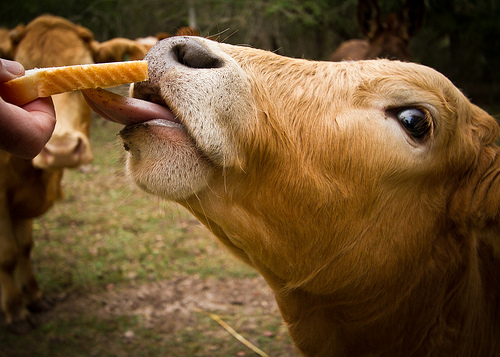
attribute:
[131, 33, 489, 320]
cow — brown, looking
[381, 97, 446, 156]
eye — brown, white, dark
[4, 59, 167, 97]
bread — brown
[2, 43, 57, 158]
hand — curled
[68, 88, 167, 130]
tongue — pink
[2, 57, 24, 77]
fingernail — clean, clear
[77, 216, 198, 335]
grass — green, brown, short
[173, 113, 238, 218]
whiskers — white, long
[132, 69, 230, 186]
mouth — white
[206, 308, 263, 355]
straw — yellow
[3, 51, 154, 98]
edge — brown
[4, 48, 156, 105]
bread — white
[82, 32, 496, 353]
animal — furry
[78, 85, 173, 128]
tongue — pink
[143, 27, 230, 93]
nose — white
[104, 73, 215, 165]
mouth area — white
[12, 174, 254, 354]
grass. — green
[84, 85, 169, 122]
tongue — red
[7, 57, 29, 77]
nail — thumb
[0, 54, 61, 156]
hand — person's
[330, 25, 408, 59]
animal — Dark brown 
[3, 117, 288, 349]
grass — green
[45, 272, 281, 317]
burn patch — big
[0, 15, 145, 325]
animal — caramel colored  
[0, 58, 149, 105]
bread — white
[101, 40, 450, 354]
cow — light brown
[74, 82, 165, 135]
tongue — long, pink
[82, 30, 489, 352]
cow — caramel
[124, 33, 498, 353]
cow — brown